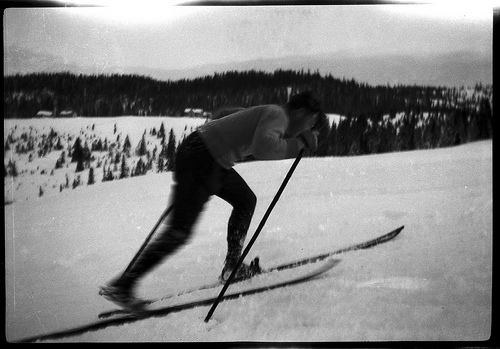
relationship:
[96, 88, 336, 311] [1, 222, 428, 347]
man on skis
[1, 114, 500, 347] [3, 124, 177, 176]
ground on trees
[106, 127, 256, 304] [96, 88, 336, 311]
black pants on man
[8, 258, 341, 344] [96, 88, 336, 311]
skies on man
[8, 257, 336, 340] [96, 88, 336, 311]
skies on man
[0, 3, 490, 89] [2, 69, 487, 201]
clouds above trees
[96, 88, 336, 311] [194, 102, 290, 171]
man wears sweater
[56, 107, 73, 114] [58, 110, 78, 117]
snow covered building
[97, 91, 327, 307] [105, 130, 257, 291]
man wearing black pants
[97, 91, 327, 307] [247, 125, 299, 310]
man holding ski pole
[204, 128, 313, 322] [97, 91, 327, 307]
ski pole held by man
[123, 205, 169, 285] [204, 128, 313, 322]
ski pole held by ski pole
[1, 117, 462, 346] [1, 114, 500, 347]
ground covered ground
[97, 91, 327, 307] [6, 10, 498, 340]
man in photograph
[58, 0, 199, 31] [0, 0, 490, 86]
sun shining in clouds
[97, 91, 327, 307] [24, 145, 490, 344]
man pushing up hill